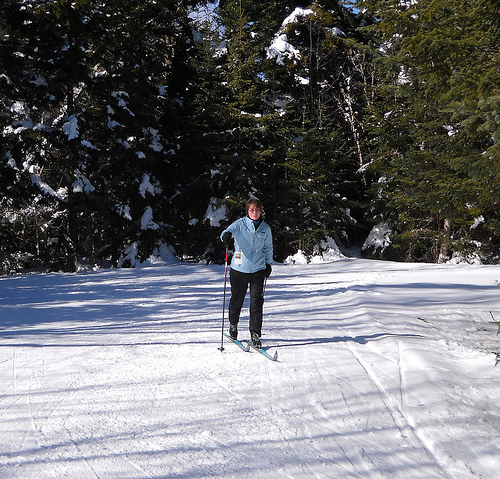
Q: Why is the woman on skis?
A: She is skiing.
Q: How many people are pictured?
A: One.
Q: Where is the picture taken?
A: Outside in the snow.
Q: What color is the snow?
A: White.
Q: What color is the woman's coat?
A: Blue.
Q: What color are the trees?
A: Green.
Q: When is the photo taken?
A: During the day.